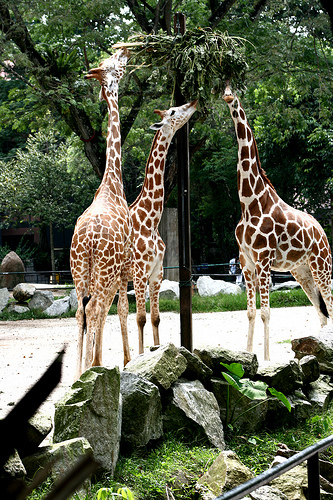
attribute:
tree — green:
[5, 127, 115, 288]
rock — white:
[195, 273, 239, 296]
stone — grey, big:
[53, 365, 124, 471]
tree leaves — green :
[268, 102, 300, 139]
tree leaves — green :
[198, 146, 227, 173]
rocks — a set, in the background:
[3, 277, 239, 316]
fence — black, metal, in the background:
[2, 263, 244, 280]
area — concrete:
[5, 311, 296, 348]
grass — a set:
[195, 288, 242, 310]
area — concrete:
[2, 318, 304, 353]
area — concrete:
[1, 314, 280, 369]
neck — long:
[225, 100, 276, 218]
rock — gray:
[160, 375, 225, 453]